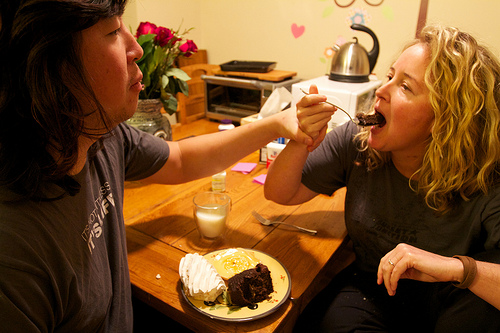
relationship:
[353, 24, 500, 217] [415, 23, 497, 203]
head of hair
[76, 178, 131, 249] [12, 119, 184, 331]
writing on a shirt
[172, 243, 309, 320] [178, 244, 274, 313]
plate of food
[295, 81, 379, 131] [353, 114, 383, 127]
fork full of food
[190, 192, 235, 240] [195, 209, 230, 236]
glass of milk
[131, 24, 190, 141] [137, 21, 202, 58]
vase full of roses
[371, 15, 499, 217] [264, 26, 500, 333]
head of a woman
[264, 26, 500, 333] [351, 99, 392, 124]
woman eating food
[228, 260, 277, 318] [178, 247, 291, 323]
snacks on a plate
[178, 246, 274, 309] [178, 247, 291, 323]
snacks on a plate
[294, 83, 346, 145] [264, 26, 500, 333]
hand on a woman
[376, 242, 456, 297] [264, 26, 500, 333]
hand on a woman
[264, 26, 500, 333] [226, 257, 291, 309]
woman eating snack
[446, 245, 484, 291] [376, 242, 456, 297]
wristwatch on a hand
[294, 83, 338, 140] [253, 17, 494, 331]
hand on a woman'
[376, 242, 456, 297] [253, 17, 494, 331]
hand on a woman'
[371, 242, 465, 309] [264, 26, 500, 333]
hand on a woman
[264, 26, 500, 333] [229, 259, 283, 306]
woman eating snack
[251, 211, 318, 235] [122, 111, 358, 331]
fork on a table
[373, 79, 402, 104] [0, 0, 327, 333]
nose on a man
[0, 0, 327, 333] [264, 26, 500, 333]
man watching a woman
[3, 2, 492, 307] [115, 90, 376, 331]
couple sitting at a table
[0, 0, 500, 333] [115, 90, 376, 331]
couple sitting at a table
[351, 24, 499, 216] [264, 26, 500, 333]
hair on a woman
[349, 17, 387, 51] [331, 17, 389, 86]
handle on a kettle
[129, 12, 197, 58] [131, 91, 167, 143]
roses in a vase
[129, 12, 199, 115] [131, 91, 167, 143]
roses in a vase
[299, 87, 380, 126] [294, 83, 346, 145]
fork in a hand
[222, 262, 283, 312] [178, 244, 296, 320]
pastries on a dish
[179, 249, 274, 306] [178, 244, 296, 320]
cake on a dish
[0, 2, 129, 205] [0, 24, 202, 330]
hair on a man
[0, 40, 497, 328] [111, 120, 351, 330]
two people at a table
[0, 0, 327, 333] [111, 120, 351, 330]
man at a table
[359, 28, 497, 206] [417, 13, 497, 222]
hair on a woman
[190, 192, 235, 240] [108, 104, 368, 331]
glass on a table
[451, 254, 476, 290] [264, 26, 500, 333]
bracelets on a woman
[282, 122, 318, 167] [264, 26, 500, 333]
wrist on a woman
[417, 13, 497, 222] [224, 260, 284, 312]
woman eating cake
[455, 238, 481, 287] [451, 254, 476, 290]
bracelets on bracelets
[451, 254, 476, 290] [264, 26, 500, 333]
bracelets on woman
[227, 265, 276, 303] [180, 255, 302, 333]
cake on a plate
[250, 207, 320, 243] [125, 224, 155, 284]
fork on table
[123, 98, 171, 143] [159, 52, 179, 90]
vase with roses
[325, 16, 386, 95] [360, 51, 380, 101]
tea pot with handle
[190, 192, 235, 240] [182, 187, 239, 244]
glass of milk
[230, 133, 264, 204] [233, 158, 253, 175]
post it note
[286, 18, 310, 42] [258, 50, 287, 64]
heart on wall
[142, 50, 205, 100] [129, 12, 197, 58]
bouquet of roses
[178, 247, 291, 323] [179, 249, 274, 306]
plate with cake